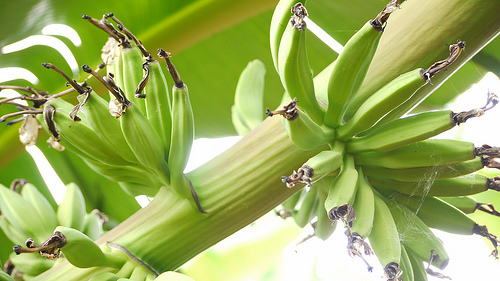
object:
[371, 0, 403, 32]
perianth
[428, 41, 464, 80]
perianth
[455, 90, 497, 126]
perianth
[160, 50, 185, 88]
perianth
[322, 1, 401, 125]
banana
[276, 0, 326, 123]
banana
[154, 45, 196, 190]
banana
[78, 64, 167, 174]
banana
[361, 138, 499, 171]
banana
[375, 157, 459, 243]
spiderweb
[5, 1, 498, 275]
plant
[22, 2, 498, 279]
limb